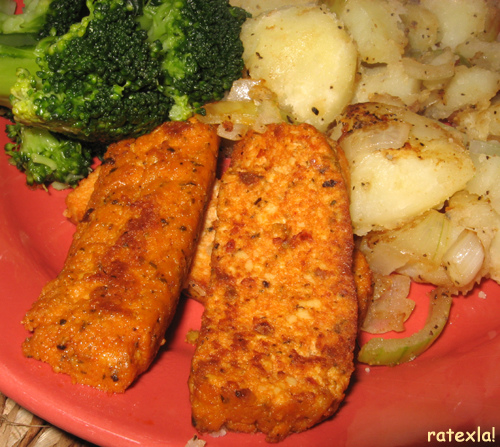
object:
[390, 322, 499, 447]
plate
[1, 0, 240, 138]
brocolli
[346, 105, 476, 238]
potatoes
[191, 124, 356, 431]
fish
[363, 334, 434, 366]
onion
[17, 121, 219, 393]
fish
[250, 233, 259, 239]
seasoning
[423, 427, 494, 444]
watermark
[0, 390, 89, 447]
table